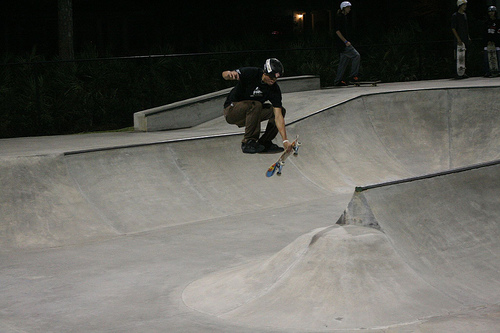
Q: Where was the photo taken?
A: It was taken at the skate park.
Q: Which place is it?
A: It is a skate park.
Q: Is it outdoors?
A: Yes, it is outdoors.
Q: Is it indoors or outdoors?
A: It is outdoors.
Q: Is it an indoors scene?
A: No, it is outdoors.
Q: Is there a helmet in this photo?
A: Yes, there is a helmet.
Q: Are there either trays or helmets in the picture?
A: Yes, there is a helmet.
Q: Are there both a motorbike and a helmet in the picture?
A: No, there is a helmet but no motorcycles.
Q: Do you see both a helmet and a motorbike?
A: No, there is a helmet but no motorcycles.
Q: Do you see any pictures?
A: No, there are no pictures.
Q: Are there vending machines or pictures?
A: No, there are no pictures or vending machines.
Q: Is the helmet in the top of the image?
A: Yes, the helmet is in the top of the image.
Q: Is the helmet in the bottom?
A: No, the helmet is in the top of the image.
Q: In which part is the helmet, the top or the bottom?
A: The helmet is in the top of the image.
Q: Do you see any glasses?
A: No, there are no glasses.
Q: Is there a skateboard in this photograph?
A: Yes, there is a skateboard.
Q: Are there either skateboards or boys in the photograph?
A: Yes, there is a skateboard.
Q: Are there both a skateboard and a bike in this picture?
A: No, there is a skateboard but no bikes.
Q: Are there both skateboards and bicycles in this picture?
A: No, there is a skateboard but no bikes.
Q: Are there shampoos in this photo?
A: No, there are no shampoos.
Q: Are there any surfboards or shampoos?
A: No, there are no shampoos or surfboards.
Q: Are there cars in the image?
A: No, there are no cars.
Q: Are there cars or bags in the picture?
A: No, there are no cars or bags.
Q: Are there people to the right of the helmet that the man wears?
A: Yes, there is a person to the right of the helmet.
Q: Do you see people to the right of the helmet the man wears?
A: Yes, there is a person to the right of the helmet.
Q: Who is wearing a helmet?
A: The man is wearing a helmet.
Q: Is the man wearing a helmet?
A: Yes, the man is wearing a helmet.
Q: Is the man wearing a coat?
A: No, the man is wearing a helmet.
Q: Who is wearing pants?
A: The man is wearing pants.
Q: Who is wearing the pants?
A: The man is wearing pants.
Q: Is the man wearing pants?
A: Yes, the man is wearing pants.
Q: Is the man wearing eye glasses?
A: No, the man is wearing pants.